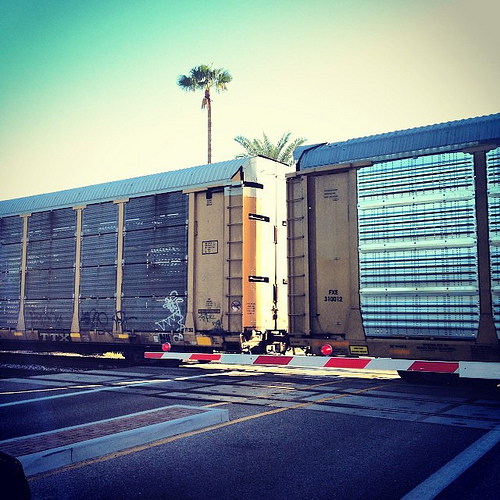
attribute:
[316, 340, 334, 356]
train indicator — train's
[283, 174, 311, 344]
metal rungs — yellow 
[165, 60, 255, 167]
tree — tall 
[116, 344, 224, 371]
train wheel — on bottom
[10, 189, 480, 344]
train — for tracks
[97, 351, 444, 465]
sidewalk — with indicator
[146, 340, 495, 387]
arm — red , white 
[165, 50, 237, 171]
tree — behind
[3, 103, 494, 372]
cars — yellow, of train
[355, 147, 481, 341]
siding — metal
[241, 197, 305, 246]
window — rectangle 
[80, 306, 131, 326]
graffiti — black 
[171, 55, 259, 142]
palm tree — tall, behind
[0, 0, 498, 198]
sky — with clouds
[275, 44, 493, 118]
cloud — dark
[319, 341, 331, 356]
light — red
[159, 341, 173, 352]
light — red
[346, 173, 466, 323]
panel — corrugated  